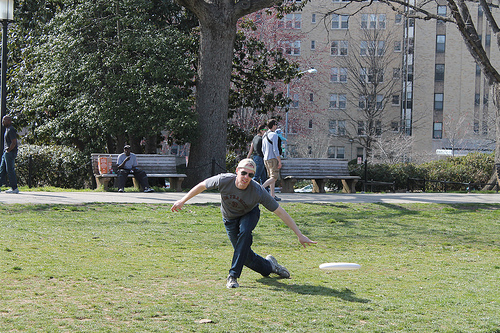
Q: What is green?
A: Grass.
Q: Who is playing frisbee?
A: The man.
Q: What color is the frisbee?
A: White.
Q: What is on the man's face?
A: Glasses.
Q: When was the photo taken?
A: Day time.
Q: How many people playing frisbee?
A: One.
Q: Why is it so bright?
A: Sunny.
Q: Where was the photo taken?
A: In a park.